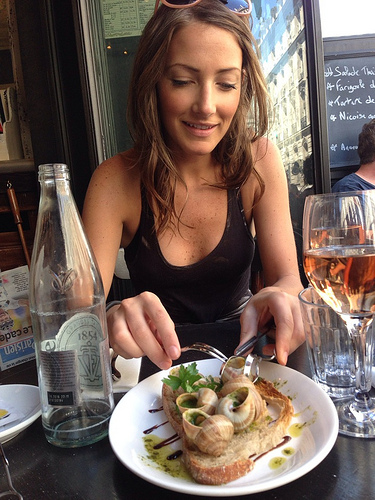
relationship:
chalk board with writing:
[324, 55, 373, 155] [320, 65, 373, 153]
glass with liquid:
[305, 313, 339, 370] [302, 244, 375, 317]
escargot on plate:
[175, 369, 261, 456] [106, 359, 338, 500]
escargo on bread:
[181, 387, 257, 453] [121, 373, 323, 478]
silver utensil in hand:
[218, 313, 278, 382] [236, 280, 310, 366]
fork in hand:
[181, 343, 228, 365] [98, 281, 183, 375]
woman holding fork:
[64, 0, 311, 368] [181, 343, 228, 365]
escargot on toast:
[215, 386, 257, 434] [159, 364, 294, 485]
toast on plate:
[159, 364, 294, 485] [286, 376, 308, 443]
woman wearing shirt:
[64, 0, 311, 368] [123, 151, 256, 324]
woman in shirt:
[64, 0, 311, 368] [123, 151, 256, 354]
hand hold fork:
[234, 280, 310, 366] [181, 343, 228, 365]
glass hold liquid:
[293, 177, 374, 426] [300, 244, 373, 317]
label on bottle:
[41, 312, 114, 410] [27, 145, 129, 455]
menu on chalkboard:
[325, 63, 374, 117] [317, 35, 374, 181]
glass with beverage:
[300, 185, 373, 439] [302, 246, 374, 316]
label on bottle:
[40, 349, 77, 410] [28, 166, 111, 456]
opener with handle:
[221, 346, 273, 382] [230, 323, 279, 361]